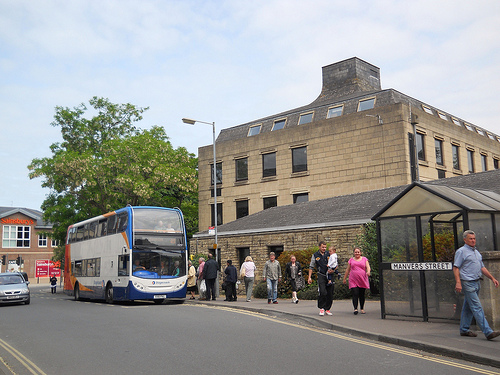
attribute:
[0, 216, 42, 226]
words — orange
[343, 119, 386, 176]
bricks — tan, tall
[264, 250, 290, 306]
person — standing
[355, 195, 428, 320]
glass — enclosed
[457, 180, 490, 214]
roof — gray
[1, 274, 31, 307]
car — silver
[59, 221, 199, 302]
bus — two leveled, two passenger, double decker, passenger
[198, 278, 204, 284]
purse — tan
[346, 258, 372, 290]
dress — pink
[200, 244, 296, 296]
people — entering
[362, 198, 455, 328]
bus stop — manvers street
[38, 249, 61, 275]
sign — red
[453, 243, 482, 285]
shirt — blue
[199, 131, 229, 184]
pole — metal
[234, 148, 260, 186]
window — rectangular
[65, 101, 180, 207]
tree — large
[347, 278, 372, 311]
pants — black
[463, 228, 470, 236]
hair — grey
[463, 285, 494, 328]
jeans — blue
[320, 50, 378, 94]
chimney — brown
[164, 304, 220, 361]
road — paved